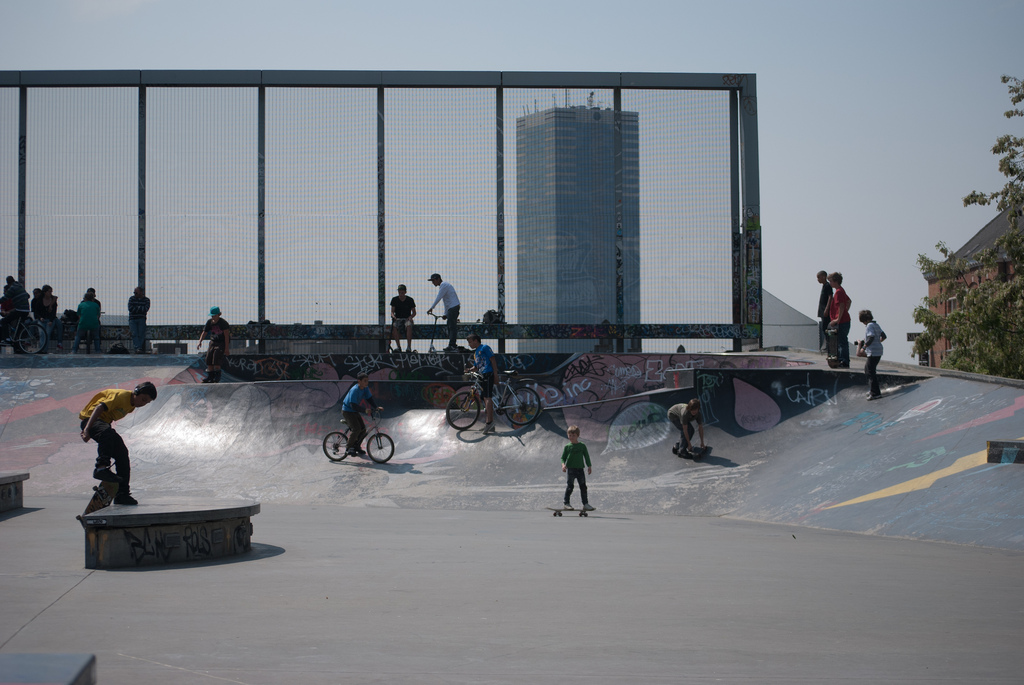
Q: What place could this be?
A: It is a skate park.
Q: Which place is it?
A: It is a skate park.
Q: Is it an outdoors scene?
A: Yes, it is outdoors.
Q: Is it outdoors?
A: Yes, it is outdoors.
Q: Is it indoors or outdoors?
A: It is outdoors.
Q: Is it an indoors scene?
A: No, it is outdoors.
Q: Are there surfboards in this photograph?
A: No, there are no surfboards.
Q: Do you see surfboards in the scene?
A: No, there are no surfboards.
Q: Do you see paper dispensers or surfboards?
A: No, there are no surfboards or paper dispensers.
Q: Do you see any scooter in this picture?
A: Yes, there is a scooter.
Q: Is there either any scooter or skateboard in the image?
A: Yes, there is a scooter.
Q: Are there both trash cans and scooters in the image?
A: No, there is a scooter but no trash cans.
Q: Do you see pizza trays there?
A: No, there are no pizza trays.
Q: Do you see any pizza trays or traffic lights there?
A: No, there are no pizza trays or traffic lights.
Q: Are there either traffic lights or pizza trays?
A: No, there are no pizza trays or traffic lights.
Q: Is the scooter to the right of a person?
A: Yes, the scooter is to the right of a person.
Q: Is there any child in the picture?
A: Yes, there is a child.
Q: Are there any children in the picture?
A: Yes, there is a child.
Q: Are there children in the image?
A: Yes, there is a child.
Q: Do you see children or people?
A: Yes, there is a child.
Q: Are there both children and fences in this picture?
A: Yes, there are both a child and a fence.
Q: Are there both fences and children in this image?
A: Yes, there are both a child and a fence.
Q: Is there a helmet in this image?
A: No, there are no helmets.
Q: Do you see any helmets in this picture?
A: No, there are no helmets.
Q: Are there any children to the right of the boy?
A: Yes, there is a child to the right of the boy.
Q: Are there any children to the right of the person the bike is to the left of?
A: Yes, there is a child to the right of the boy.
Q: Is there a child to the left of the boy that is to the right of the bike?
A: No, the child is to the right of the boy.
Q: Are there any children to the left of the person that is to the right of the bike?
A: No, the child is to the right of the boy.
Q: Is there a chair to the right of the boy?
A: No, there is a child to the right of the boy.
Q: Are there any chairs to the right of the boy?
A: No, there is a child to the right of the boy.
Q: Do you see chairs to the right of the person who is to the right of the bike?
A: No, there is a child to the right of the boy.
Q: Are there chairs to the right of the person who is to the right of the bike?
A: No, there is a child to the right of the boy.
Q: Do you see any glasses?
A: No, there are no glasses.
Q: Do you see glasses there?
A: No, there are no glasses.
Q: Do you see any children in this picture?
A: Yes, there is a child.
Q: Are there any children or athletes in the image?
A: Yes, there is a child.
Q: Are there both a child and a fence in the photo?
A: Yes, there are both a child and a fence.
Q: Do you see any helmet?
A: No, there are no helmets.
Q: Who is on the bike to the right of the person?
A: The kid is on the bike.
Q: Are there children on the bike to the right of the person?
A: Yes, there is a child on the bike.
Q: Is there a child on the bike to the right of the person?
A: Yes, there is a child on the bike.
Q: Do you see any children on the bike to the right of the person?
A: Yes, there is a child on the bike.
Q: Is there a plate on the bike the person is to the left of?
A: No, there is a child on the bike.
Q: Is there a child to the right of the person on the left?
A: Yes, there is a child to the right of the person.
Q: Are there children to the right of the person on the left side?
A: Yes, there is a child to the right of the person.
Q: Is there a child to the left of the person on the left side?
A: No, the child is to the right of the person.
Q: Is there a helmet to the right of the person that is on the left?
A: No, there is a child to the right of the person.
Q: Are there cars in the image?
A: No, there are no cars.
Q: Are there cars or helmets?
A: No, there are no cars or helmets.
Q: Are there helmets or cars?
A: No, there are no cars or helmets.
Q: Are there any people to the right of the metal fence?
A: Yes, there is a person to the right of the fence.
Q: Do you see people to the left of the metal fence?
A: No, the person is to the right of the fence.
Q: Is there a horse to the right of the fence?
A: No, there is a person to the right of the fence.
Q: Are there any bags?
A: No, there are no bags.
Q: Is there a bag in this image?
A: No, there are no bags.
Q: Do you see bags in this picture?
A: No, there are no bags.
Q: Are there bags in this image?
A: No, there are no bags.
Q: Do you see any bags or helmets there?
A: No, there are no bags or helmets.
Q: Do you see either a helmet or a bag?
A: No, there are no bags or helmets.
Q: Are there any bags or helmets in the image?
A: No, there are no bags or helmets.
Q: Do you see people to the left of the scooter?
A: Yes, there is a person to the left of the scooter.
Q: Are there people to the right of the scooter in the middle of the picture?
A: No, the person is to the left of the scooter.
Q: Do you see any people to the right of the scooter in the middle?
A: No, the person is to the left of the scooter.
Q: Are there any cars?
A: No, there are no cars.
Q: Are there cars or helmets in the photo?
A: No, there are no cars or helmets.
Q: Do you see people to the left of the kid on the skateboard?
A: Yes, there is a person to the left of the kid.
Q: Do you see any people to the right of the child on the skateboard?
A: No, the person is to the left of the kid.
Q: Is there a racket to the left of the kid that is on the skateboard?
A: No, there is a person to the left of the kid.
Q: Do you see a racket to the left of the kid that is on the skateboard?
A: No, there is a person to the left of the kid.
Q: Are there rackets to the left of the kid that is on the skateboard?
A: No, there is a person to the left of the kid.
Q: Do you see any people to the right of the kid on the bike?
A: Yes, there is a person to the right of the child.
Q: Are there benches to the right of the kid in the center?
A: No, there is a person to the right of the child.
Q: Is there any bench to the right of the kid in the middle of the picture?
A: No, there is a person to the right of the child.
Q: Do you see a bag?
A: No, there are no bags.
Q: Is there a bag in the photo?
A: No, there are no bags.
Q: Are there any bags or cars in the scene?
A: No, there are no bags or cars.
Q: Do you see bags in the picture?
A: No, there are no bags.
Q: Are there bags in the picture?
A: No, there are no bags.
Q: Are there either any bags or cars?
A: No, there are no bags or cars.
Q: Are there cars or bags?
A: No, there are no bags or cars.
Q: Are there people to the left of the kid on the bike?
A: Yes, there is a person to the left of the child.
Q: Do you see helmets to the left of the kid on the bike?
A: No, there is a person to the left of the child.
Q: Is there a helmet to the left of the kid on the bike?
A: No, there is a person to the left of the child.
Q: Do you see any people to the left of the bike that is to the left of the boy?
A: Yes, there is a person to the left of the bike.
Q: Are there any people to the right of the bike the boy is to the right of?
A: No, the person is to the left of the bike.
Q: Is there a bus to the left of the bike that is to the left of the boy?
A: No, there is a person to the left of the bike.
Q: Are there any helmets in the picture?
A: No, there are no helmets.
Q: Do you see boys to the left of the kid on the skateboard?
A: Yes, there is a boy to the left of the child.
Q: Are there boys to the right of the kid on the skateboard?
A: No, the boy is to the left of the child.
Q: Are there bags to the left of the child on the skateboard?
A: No, there is a boy to the left of the kid.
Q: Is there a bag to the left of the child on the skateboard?
A: No, there is a boy to the left of the kid.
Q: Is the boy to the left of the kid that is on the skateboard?
A: Yes, the boy is to the left of the kid.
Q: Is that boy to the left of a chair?
A: No, the boy is to the left of the kid.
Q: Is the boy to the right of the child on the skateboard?
A: No, the boy is to the left of the kid.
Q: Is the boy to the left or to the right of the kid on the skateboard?
A: The boy is to the left of the kid.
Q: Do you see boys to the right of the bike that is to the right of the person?
A: Yes, there is a boy to the right of the bike.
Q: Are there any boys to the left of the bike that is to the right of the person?
A: No, the boy is to the right of the bike.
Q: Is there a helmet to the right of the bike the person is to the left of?
A: No, there is a boy to the right of the bike.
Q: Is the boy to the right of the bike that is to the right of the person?
A: Yes, the boy is to the right of the bike.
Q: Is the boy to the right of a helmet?
A: No, the boy is to the right of the bike.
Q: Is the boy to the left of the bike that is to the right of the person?
A: No, the boy is to the right of the bike.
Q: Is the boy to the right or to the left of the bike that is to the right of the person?
A: The boy is to the right of the bike.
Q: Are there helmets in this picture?
A: No, there are no helmets.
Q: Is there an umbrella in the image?
A: No, there are no umbrellas.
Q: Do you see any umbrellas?
A: No, there are no umbrellas.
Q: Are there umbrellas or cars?
A: No, there are no umbrellas or cars.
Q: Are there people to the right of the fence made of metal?
A: Yes, there are people to the right of the fence.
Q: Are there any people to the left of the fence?
A: No, the people are to the right of the fence.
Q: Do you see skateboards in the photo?
A: Yes, there is a skateboard.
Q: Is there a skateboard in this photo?
A: Yes, there is a skateboard.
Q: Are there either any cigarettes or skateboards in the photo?
A: Yes, there is a skateboard.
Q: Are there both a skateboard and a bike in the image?
A: Yes, there are both a skateboard and a bike.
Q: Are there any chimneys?
A: No, there are no chimneys.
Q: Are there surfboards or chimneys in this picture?
A: No, there are no chimneys or surfboards.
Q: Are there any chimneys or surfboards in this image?
A: No, there are no chimneys or surfboards.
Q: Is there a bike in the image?
A: Yes, there is a bike.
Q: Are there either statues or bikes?
A: Yes, there is a bike.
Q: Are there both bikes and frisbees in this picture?
A: No, there is a bike but no frisbees.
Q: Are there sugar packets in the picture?
A: No, there are no sugar packets.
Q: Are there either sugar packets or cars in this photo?
A: No, there are no sugar packets or cars.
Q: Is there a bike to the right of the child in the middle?
A: Yes, there is a bike to the right of the kid.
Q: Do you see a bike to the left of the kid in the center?
A: No, the bike is to the right of the kid.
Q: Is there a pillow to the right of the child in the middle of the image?
A: No, there is a bike to the right of the child.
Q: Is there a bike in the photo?
A: Yes, there is a bike.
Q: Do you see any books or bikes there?
A: Yes, there is a bike.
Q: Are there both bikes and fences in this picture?
A: Yes, there are both a bike and a fence.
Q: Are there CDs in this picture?
A: No, there are no cds.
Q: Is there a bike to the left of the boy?
A: Yes, there is a bike to the left of the boy.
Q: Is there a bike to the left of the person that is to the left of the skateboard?
A: Yes, there is a bike to the left of the boy.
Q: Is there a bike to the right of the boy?
A: No, the bike is to the left of the boy.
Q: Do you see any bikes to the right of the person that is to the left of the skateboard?
A: No, the bike is to the left of the boy.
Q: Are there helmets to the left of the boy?
A: No, there is a bike to the left of the boy.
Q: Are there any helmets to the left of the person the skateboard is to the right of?
A: No, there is a bike to the left of the boy.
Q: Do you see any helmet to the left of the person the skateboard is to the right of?
A: No, there is a bike to the left of the boy.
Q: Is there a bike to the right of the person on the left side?
A: Yes, there is a bike to the right of the person.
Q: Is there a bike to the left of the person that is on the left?
A: No, the bike is to the right of the person.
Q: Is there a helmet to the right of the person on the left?
A: No, there is a bike to the right of the person.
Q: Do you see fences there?
A: Yes, there is a fence.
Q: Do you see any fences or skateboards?
A: Yes, there is a fence.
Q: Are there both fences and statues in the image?
A: No, there is a fence but no statues.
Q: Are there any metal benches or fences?
A: Yes, there is a metal fence.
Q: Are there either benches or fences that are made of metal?
A: Yes, the fence is made of metal.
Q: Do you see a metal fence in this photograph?
A: Yes, there is a metal fence.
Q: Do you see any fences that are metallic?
A: Yes, there is a fence that is metallic.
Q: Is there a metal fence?
A: Yes, there is a fence that is made of metal.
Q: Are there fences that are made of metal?
A: Yes, there is a fence that is made of metal.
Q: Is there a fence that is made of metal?
A: Yes, there is a fence that is made of metal.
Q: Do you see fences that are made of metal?
A: Yes, there is a fence that is made of metal.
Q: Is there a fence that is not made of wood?
A: Yes, there is a fence that is made of metal.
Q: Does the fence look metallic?
A: Yes, the fence is metallic.